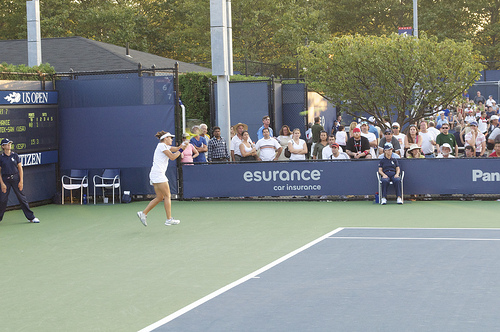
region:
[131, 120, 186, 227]
Woman on a tennis court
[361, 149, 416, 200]
Man sitting in a chair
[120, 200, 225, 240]
Woman jumping off the ground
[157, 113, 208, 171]
Woman swinging a tennis racket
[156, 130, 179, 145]
Woman wearing a white hat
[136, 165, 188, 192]
woman wearing white shorts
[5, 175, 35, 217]
Man wearing blue pants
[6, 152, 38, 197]
Man wearing a blue shirt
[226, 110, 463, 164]
People watching a tennis match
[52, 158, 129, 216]
Two chairs together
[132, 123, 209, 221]
tennis player swinging at ball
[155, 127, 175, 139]
white visor of tennis player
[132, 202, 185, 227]
white shoes of tennis player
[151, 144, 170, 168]
white shirt of tennis player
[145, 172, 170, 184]
white skirt of tennis player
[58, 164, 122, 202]
two white and blue chairs against wall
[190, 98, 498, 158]
crowd watching the tennis match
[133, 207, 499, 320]
blue court with white lines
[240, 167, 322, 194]
white lettering on blue background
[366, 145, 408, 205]
court attendant sitting in chair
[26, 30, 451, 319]
this picture is outside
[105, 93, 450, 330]
this picture is on a tennis court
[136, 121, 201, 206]
this lady is a tennis player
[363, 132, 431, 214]
this man is a referee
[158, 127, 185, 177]
the woman is wearing white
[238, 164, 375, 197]
this says "esurance"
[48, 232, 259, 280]
the court is made of clay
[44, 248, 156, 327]
the court is green here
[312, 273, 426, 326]
the court is blue here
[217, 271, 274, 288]
the line is white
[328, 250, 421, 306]
the court is blue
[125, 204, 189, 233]
the shoes are white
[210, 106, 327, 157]
the people are standing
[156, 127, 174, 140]
the visor is white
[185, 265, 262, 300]
the line is white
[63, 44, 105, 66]
the roof is black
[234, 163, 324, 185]
the word is white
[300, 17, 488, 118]
the tree is small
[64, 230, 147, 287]
the court is green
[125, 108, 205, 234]
the woman is playing tennis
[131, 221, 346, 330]
white line on the tennis court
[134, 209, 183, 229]
white and gray tennis shoes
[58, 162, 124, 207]
white and blue chairs on the court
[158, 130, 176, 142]
white visor on the player's head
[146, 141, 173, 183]
white uniform on the player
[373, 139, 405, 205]
ball woman sitting in a chair on the court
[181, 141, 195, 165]
woman wearing a light pink shirt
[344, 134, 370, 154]
man wearing a black shirt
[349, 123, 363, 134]
man wearing a red hat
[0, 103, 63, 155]
black and yellow scoreboard